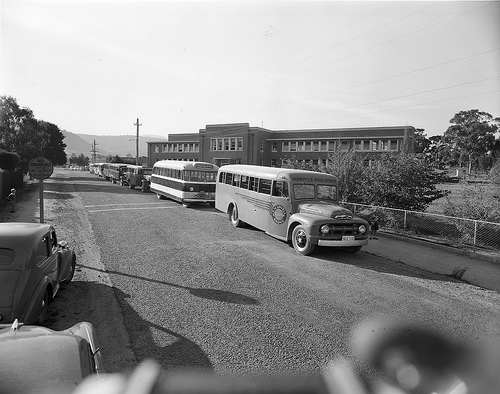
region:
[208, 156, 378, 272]
an old bus on side of a street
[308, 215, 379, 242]
old bus has two headlights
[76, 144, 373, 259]
a line of buses on side of street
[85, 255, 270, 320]
shadow on street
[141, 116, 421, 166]
a building behind the buses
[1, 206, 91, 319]
an old card parking in front of buses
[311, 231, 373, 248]
plate of bus over a bumper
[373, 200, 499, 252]
rail on side of bus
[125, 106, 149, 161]
a pole in front of business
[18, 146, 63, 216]
a street sign in front an old car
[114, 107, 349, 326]
buses lined up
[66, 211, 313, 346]
a shadow casted on the street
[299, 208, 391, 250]
the front of the bus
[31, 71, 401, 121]
the bunch of clouds in the sky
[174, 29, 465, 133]
the wires in the area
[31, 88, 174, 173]
mountains all the wya in the back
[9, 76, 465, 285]
a black and white photo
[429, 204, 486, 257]
a fence on the side of the road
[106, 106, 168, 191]
electric poles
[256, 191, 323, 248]
the logo of the bus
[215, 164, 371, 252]
A gray school van.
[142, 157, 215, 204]
A black and white school bus.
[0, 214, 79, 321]
A small car in picture.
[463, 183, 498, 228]
Flowers in the picture.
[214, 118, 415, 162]
A building in the photo.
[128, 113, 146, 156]
An electric pole in the photo.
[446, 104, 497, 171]
A tree in the picture.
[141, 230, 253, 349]
A road with tarmac in the picture.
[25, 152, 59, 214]
A road sign in the photo.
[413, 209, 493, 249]
A mesh wire near the road.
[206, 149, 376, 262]
a bus parked on a street.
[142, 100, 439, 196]
a multi story building.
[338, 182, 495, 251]
a small chain link fence.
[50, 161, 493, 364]
a dirt road near a building.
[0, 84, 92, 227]
a leafy green tree.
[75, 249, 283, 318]
a shadow cast by a sign.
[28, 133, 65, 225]
a sign on the side of a road.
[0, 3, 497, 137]
a hazy gray sky.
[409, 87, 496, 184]
a leaf filled tree.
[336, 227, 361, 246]
a license plate.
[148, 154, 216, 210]
An old bus behind a smaller bus.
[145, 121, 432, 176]
Large brick building behind buses.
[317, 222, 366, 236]
Two headlights on the front of the first bus.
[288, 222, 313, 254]
Front wheel on a bus in front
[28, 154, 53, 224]
A round sign on the left of the street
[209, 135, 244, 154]
Top five windows on the front of a brick building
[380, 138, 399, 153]
Last two windows on the right upper side of a building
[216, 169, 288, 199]
Windows on the side of an old front bus.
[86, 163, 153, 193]
Line of old buses behind the first two buses.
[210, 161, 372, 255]
Old bus with circle on the door.